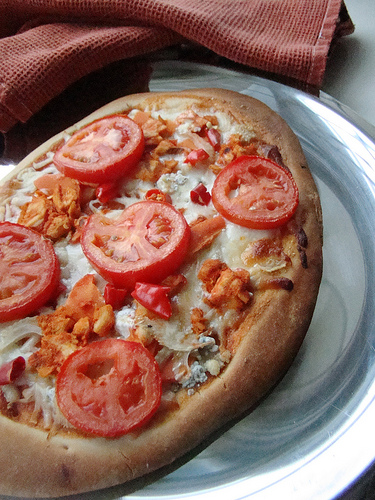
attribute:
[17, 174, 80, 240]
pizza topping — brown colored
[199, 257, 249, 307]
pizza topping — brown colored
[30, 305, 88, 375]
pizza topping — brown colored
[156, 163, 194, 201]
cheese — feta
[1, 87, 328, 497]
pizza topping — brown colored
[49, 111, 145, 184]
tomato — red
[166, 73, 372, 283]
plate — silver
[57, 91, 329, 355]
pizza — brown colored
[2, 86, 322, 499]
crust — golden brown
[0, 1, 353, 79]
cloth — folded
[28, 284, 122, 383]
meat — topping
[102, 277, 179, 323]
pepper — red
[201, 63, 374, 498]
plate — hot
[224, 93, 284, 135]
crust — pizza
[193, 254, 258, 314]
topping — brown colored, pizza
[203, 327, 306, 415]
crust — brown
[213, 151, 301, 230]
tomato — red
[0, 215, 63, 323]
tomato — red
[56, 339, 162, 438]
tomato — red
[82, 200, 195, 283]
tomato — red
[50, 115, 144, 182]
tomato — red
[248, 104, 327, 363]
crust — golden brown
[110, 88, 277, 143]
crust — golden brown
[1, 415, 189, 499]
crust — golden brown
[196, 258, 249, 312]
topping — brown colored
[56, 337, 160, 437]
topping — brown colored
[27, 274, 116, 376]
topping — brown colored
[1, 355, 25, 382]
topping — brown colored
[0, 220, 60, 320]
topping — brown colored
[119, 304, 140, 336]
cheese — white, melted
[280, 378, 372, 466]
tray — silver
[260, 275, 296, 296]
cheese — burnt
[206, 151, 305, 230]
topping — brown colored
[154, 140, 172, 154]
pizza topping — brown colored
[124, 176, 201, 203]
cheese — white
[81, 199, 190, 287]
tomato slice — red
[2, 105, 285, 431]
cheese — white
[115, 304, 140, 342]
cheese — blue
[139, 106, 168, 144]
topping — brown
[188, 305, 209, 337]
topping — brown colored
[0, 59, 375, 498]
plate — silver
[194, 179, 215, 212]
peppers — diced